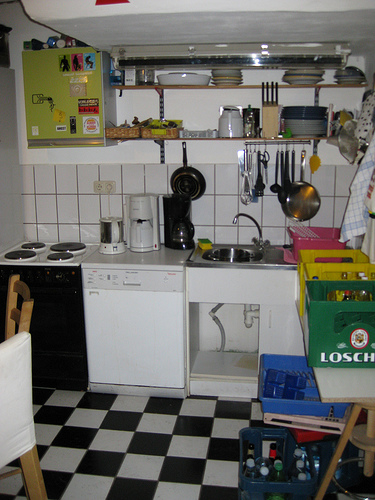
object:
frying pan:
[170, 141, 206, 200]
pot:
[280, 150, 320, 221]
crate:
[303, 280, 374, 368]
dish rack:
[286, 227, 349, 261]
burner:
[47, 252, 74, 261]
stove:
[1, 241, 98, 392]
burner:
[4, 250, 36, 260]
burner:
[21, 242, 44, 250]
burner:
[51, 243, 85, 251]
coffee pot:
[124, 193, 164, 253]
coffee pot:
[162, 193, 195, 250]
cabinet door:
[23, 46, 106, 149]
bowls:
[282, 68, 324, 85]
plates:
[280, 105, 327, 136]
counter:
[81, 244, 194, 271]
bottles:
[243, 441, 310, 480]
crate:
[237, 426, 317, 498]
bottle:
[268, 443, 278, 458]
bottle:
[246, 444, 256, 460]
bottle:
[289, 451, 303, 473]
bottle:
[243, 458, 257, 479]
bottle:
[256, 456, 272, 477]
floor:
[0, 385, 338, 499]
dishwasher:
[81, 244, 195, 399]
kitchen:
[0, 1, 373, 500]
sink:
[202, 246, 264, 262]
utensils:
[241, 141, 294, 205]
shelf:
[109, 136, 335, 141]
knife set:
[260, 81, 280, 138]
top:
[1, 241, 99, 267]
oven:
[0, 264, 88, 390]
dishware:
[111, 62, 367, 83]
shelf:
[109, 82, 368, 89]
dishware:
[106, 82, 357, 135]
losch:
[319, 352, 374, 364]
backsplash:
[21, 164, 360, 244]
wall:
[1, 1, 366, 247]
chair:
[3, 274, 35, 340]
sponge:
[198, 238, 213, 250]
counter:
[260, 245, 356, 270]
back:
[0, 336, 35, 471]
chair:
[0, 332, 48, 500]